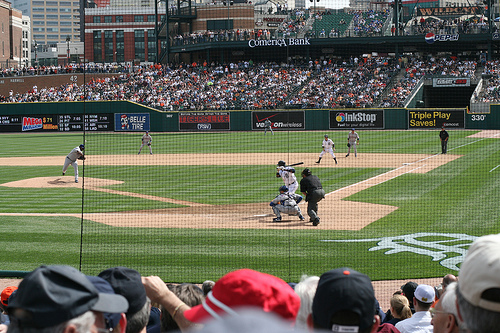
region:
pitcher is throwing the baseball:
[58, 126, 104, 207]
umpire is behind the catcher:
[295, 162, 333, 217]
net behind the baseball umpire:
[69, 35, 414, 266]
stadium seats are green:
[315, 8, 349, 38]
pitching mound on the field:
[13, 165, 119, 190]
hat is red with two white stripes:
[205, 269, 307, 328]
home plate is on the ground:
[246, 199, 282, 239]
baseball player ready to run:
[310, 118, 348, 180]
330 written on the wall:
[471, 111, 485, 124]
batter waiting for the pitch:
[273, 154, 319, 208]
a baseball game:
[0, 2, 498, 332]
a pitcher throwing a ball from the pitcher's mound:
[57, 142, 89, 186]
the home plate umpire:
[296, 167, 323, 223]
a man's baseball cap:
[2, 260, 123, 325]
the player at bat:
[271, 155, 297, 190]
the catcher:
[270, 185, 305, 221]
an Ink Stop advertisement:
[330, 110, 380, 125]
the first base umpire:
[435, 120, 446, 152]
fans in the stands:
[13, 58, 424, 98]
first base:
[404, 161, 416, 167]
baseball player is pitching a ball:
[57, 141, 88, 183]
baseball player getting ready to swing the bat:
[273, 157, 304, 188]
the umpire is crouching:
[265, 184, 305, 224]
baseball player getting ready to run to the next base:
[314, 133, 337, 167]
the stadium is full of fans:
[5, 63, 496, 107]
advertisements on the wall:
[0, 107, 469, 132]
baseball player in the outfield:
[258, 115, 275, 137]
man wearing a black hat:
[6, 271, 123, 331]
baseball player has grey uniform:
[59, 144, 84, 182]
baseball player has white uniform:
[270, 163, 302, 194]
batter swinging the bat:
[266, 151, 316, 223]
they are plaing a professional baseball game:
[16, 16, 488, 320]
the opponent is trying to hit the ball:
[246, 136, 334, 231]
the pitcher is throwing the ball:
[45, 142, 107, 194]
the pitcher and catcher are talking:
[45, 131, 353, 243]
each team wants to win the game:
[39, 129, 413, 236]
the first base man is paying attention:
[309, 122, 409, 172]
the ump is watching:
[289, 159, 329, 230]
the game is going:
[35, 25, 476, 307]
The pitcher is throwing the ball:
[55, 140, 91, 182]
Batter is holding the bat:
[271, 157, 308, 194]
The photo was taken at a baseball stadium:
[1, 1, 499, 331]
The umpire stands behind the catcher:
[297, 166, 329, 231]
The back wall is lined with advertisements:
[1, 111, 463, 132]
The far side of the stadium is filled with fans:
[0, 1, 499, 109]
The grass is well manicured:
[0, 127, 496, 277]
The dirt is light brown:
[0, 150, 458, 231]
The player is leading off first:
[310, 127, 340, 168]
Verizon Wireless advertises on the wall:
[250, 108, 305, 130]